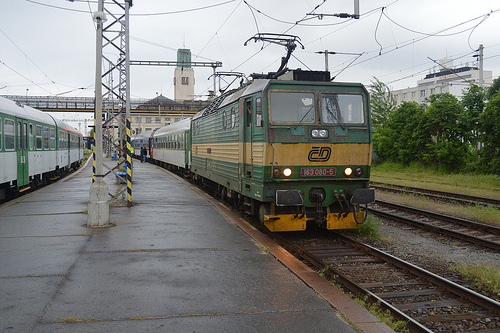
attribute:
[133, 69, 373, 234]
train — green, stopped, picking, yellow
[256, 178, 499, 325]
railroad — three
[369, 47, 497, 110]
building — white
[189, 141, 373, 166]
stripe — yellow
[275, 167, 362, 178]
headlights — on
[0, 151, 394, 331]
ground — wet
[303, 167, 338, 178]
plate — red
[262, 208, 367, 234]
stoppers — yellow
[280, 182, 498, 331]
track — metal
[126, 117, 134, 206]
pole — yellow, grey